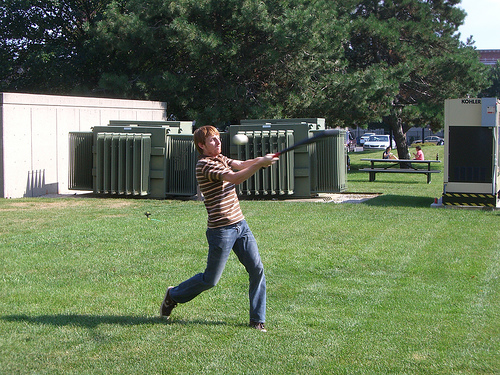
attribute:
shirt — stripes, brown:
[196, 153, 250, 222]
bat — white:
[267, 118, 348, 165]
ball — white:
[228, 130, 271, 160]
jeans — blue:
[184, 223, 275, 326]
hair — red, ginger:
[187, 122, 227, 150]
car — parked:
[356, 126, 395, 158]